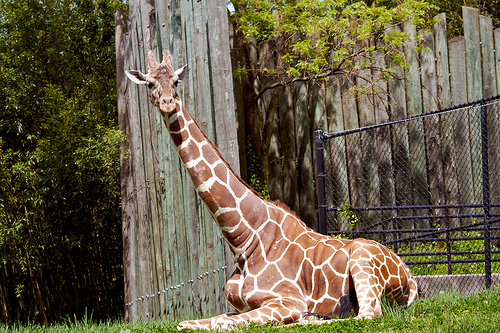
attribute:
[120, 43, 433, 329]
giraffe — captured, brown, caputred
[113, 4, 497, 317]
fence — wooden, uneven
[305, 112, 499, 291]
gate — black, metal, big, wooden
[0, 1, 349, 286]
trees — green, brown